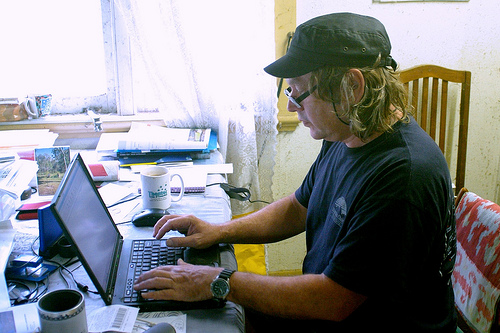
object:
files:
[119, 155, 193, 168]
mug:
[139, 166, 184, 208]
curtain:
[123, 0, 276, 213]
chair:
[397, 65, 472, 196]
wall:
[388, 5, 493, 75]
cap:
[251, 9, 417, 100]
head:
[286, 12, 401, 144]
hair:
[312, 63, 407, 139]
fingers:
[155, 214, 193, 240]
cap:
[263, 12, 398, 79]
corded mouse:
[131, 208, 171, 227]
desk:
[2, 122, 247, 333]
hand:
[133, 258, 225, 302]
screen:
[115, 0, 281, 125]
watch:
[209, 267, 238, 303]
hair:
[242, 278, 327, 309]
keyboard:
[123, 239, 219, 306]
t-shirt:
[287, 119, 462, 331]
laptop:
[49, 152, 226, 313]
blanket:
[456, 192, 498, 329]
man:
[132, 12, 458, 332]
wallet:
[15, 199, 51, 220]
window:
[112, 5, 277, 126]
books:
[125, 121, 213, 151]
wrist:
[212, 267, 249, 303]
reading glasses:
[278, 84, 323, 106]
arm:
[216, 173, 445, 322]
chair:
[452, 188, 500, 332]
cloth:
[455, 195, 483, 318]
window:
[0, 0, 113, 115]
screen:
[61, 167, 118, 296]